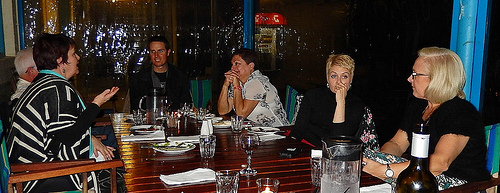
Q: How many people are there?
A: Six.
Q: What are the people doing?
A: Sitting around.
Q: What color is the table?
A: Brown.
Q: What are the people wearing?
A: Clothes.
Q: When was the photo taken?
A: At night.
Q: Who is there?
A: Men and women.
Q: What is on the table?
A: Glass.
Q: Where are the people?
A: At a restaurant.